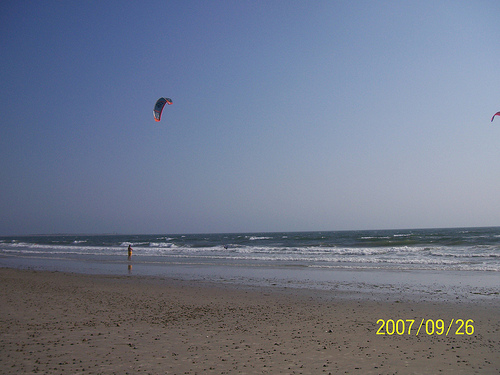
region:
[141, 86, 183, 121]
kite in air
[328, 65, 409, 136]
white clouds n blue sky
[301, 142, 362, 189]
white clouds n blue sky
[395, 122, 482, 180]
white clouds n blue sky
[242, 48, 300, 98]
white clouds n blue sky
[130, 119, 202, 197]
white clouds n blue sky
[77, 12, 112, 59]
white clouds n blue sky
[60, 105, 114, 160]
white clouds n blue sky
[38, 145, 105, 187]
white clouds n blue sky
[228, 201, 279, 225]
white clouds n blue sky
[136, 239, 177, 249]
large wave in ocean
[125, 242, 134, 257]
person standing in water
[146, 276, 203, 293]
patch of wet sand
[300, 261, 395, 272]
tide coming into shore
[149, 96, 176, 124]
red parachute in sky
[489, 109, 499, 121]
colored parachute over water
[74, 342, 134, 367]
patch of dry sand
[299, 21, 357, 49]
clear light blue sky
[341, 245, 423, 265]
waves crashing into shore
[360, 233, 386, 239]
waves starting off shore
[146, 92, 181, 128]
High flying kite in ski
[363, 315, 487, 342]
Date stamp on photo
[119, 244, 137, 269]
Kite flyer on beach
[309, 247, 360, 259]
Churning white ocean water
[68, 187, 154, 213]
Hazy blue ocean sky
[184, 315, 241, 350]
Footprints on sandy beach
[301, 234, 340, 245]
Deep blue ocean water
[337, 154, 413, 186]
Hazy light blue sky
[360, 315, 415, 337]
Year picture was taken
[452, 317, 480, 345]
Day photograph was taken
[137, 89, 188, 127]
kite in the air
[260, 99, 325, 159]
white clouds in blue sky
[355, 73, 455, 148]
white clouds in blue sky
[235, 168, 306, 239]
white clouds in blue sky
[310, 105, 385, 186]
white clouds in blue sky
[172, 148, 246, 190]
white clouds in blue sky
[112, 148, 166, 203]
white clouds in blue sky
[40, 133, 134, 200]
white clouds in blue sky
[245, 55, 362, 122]
white clouds in blue sky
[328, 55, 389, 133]
white clouds in blue sky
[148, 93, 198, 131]
kite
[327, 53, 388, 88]
white clouds in the blue sky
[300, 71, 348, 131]
white clouds in the blue sky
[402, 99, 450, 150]
white clouds in the blue sky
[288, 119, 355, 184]
white clouds in the blue sky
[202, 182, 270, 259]
white clouds in the blue sky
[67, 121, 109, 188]
white clouds in the blue sky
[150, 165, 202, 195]
white clouds in the blue sky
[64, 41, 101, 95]
white clouds in the blue sky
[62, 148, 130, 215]
white clouds in the blue sky